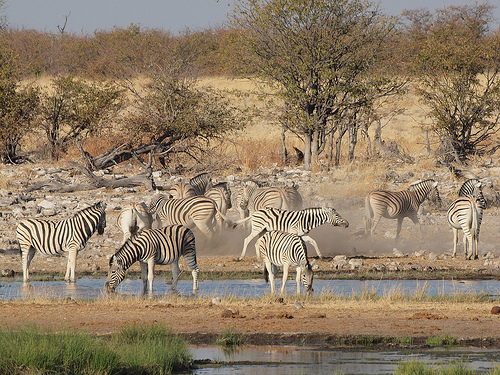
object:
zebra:
[103, 223, 200, 295]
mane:
[298, 234, 310, 263]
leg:
[145, 254, 156, 296]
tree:
[25, 68, 128, 165]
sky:
[0, 2, 500, 38]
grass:
[0, 319, 193, 374]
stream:
[178, 344, 500, 373]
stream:
[0, 277, 500, 299]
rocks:
[43, 210, 57, 218]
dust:
[312, 210, 384, 261]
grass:
[387, 330, 477, 350]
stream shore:
[0, 293, 500, 351]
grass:
[0, 73, 500, 177]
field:
[3, 0, 500, 374]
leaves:
[132, 46, 140, 52]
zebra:
[232, 206, 347, 261]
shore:
[0, 221, 500, 270]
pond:
[176, 339, 500, 374]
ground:
[0, 297, 500, 344]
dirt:
[0, 300, 500, 342]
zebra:
[257, 230, 313, 296]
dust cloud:
[314, 221, 389, 261]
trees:
[0, 24, 500, 82]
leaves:
[153, 110, 169, 116]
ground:
[0, 72, 500, 279]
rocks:
[37, 200, 59, 209]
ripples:
[183, 345, 500, 374]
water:
[0, 274, 500, 301]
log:
[25, 154, 160, 198]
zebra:
[16, 200, 108, 283]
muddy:
[179, 330, 500, 375]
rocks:
[329, 254, 347, 270]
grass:
[0, 281, 500, 312]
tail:
[365, 192, 373, 232]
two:
[54, 231, 82, 287]